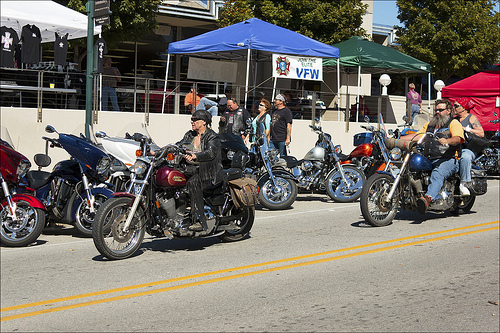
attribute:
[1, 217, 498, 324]
lines — yellow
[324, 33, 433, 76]
canopy — green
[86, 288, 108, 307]
lines — yellow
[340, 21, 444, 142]
tent — green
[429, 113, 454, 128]
beard — long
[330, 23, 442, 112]
canopy — green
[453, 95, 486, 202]
woman — red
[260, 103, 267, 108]
shades — black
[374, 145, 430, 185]
ground — blue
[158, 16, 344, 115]
canopy — blue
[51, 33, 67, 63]
shirt — black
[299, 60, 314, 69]
word — blue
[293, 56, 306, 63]
word — blue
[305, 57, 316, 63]
word — blue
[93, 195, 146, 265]
wheel — front wheel